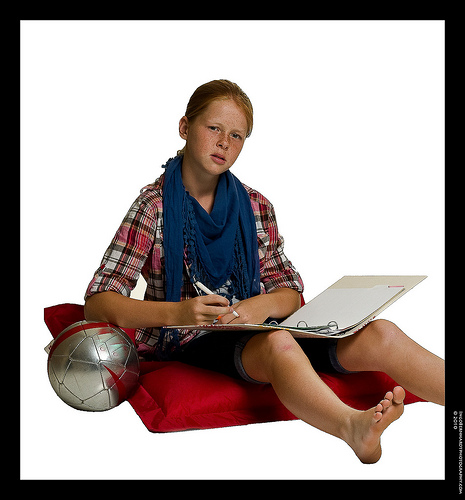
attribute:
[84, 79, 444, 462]
girl — writing, shoeless, studying, teenage, sitting, barefoot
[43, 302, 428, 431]
pillow — red, large, big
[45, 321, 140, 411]
ball — red, silver, shining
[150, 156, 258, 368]
scarf — blue, dark blue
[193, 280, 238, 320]
pen — white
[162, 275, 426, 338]
note book — pronged, ivory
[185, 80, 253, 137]
red hair — ginger colored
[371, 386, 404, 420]
toes — stinky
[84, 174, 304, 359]
shirt — plaid, red, white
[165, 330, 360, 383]
shorts — denim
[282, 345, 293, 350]
scar — red